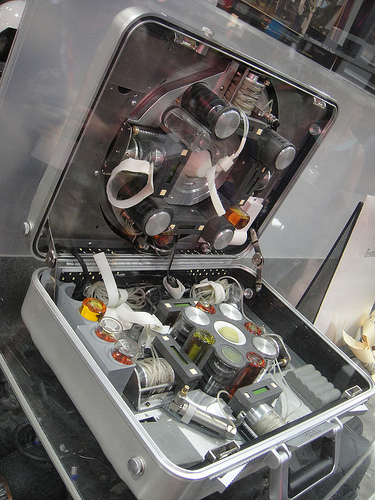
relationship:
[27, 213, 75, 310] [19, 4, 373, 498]
hinge on gray suitcase